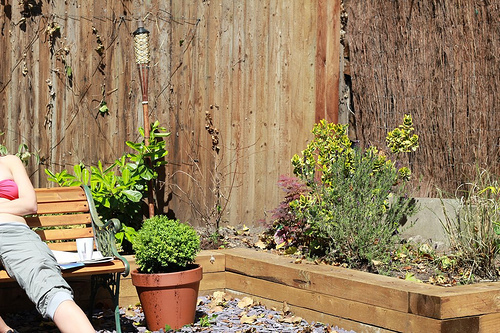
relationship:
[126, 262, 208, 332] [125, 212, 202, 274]
pot with plant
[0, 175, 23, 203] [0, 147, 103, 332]
top on woman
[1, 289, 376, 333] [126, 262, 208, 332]
gravel near pot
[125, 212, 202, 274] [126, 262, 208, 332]
plant in pot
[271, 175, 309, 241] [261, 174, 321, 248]
purple part bush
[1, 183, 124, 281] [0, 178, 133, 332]
wood metal bench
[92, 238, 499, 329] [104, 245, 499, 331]
wooden flower bed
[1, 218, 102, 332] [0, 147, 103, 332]
leg of woman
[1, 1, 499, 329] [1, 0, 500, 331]
picture during day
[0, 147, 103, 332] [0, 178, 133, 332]
woman on bench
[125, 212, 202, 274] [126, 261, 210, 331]
plant in planter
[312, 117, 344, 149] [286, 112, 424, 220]
yellow flower plant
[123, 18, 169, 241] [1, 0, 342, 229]
torch by fence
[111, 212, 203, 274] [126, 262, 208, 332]
plant in pot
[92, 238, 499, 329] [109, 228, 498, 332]
wooden flower box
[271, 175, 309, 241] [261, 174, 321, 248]
purple small bush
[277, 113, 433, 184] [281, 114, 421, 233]
flowers on bush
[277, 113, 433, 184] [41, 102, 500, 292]
flowers and plants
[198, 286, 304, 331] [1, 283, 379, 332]
leaves on ground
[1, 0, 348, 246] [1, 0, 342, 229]
wooden privacy fence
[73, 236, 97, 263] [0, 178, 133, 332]
cup on bench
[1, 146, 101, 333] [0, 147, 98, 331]
half of person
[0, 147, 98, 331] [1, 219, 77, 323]
person wearing pants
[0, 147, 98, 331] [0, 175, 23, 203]
person wearing top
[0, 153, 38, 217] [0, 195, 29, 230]
arm on stomach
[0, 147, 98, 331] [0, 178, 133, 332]
person on bench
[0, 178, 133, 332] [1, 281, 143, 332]
bench casting shadow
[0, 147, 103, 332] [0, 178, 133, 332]
lady on bench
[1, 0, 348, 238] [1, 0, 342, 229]
front of fence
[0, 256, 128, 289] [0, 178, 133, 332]
edge of bench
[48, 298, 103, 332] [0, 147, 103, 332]
calf of woman